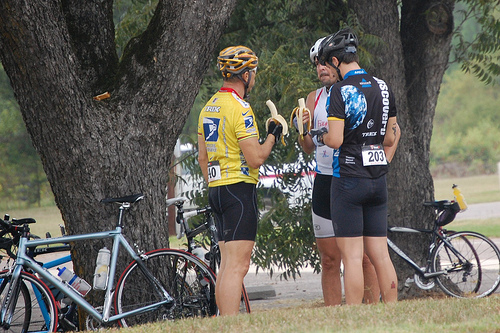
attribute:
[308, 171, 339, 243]
shorts — black, white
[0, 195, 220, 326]
bikes — resting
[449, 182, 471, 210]
bottle — yellow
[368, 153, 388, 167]
number — 40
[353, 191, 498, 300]
bike — resting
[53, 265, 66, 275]
top — blue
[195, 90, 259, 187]
shirt — yellow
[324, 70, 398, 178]
shirt — black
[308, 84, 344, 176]
shirt — white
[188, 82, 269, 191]
shirt — yellow